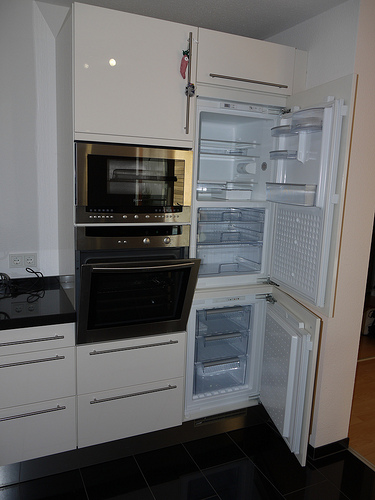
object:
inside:
[218, 263, 244, 274]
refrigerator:
[184, 23, 358, 470]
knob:
[164, 236, 171, 243]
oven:
[75, 138, 201, 345]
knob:
[142, 237, 150, 244]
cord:
[0, 267, 46, 302]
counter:
[0, 282, 77, 322]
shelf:
[201, 147, 267, 163]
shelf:
[198, 181, 258, 193]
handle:
[206, 308, 243, 315]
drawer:
[198, 310, 252, 335]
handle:
[205, 332, 242, 341]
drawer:
[195, 337, 246, 364]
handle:
[203, 358, 239, 368]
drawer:
[195, 361, 249, 399]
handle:
[90, 384, 178, 406]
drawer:
[77, 376, 187, 449]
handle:
[89, 340, 179, 358]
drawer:
[77, 339, 186, 400]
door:
[267, 71, 359, 322]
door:
[257, 287, 320, 470]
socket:
[24, 254, 34, 265]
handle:
[92, 262, 195, 271]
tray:
[262, 176, 316, 187]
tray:
[266, 147, 301, 159]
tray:
[270, 122, 297, 137]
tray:
[290, 116, 324, 126]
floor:
[1, 404, 375, 498]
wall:
[2, 0, 62, 280]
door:
[76, 257, 201, 349]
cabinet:
[190, 283, 264, 399]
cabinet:
[191, 25, 305, 103]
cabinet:
[74, 327, 190, 452]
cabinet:
[1, 317, 82, 470]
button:
[89, 215, 93, 218]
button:
[93, 215, 96, 218]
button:
[97, 215, 101, 218]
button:
[102, 215, 105, 218]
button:
[106, 215, 109, 218]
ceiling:
[122, 0, 347, 6]